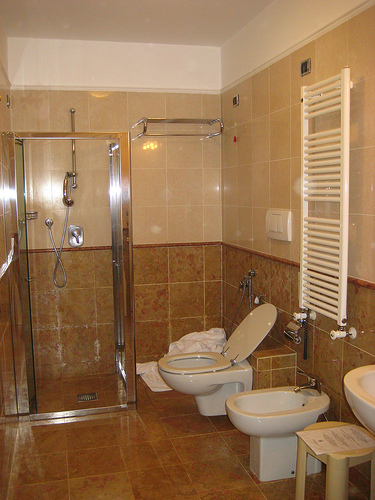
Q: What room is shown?
A: It is a bathroom.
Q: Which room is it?
A: It is a bathroom.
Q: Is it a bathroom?
A: Yes, it is a bathroom.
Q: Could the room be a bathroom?
A: Yes, it is a bathroom.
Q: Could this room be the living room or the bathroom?
A: It is the bathroom.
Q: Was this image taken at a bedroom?
A: No, the picture was taken in a bathroom.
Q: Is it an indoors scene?
A: Yes, it is indoors.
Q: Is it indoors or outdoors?
A: It is indoors.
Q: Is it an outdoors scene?
A: No, it is indoors.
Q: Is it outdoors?
A: No, it is indoors.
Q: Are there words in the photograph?
A: Yes, there are words.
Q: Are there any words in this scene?
A: Yes, there are words.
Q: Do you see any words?
A: Yes, there are words.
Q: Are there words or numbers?
A: Yes, there are words.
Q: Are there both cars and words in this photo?
A: No, there are words but no cars.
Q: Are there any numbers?
A: No, there are no numbers.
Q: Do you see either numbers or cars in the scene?
A: No, there are no numbers or cars.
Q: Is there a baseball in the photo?
A: No, there are no baseballs.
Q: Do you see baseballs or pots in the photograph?
A: No, there are no baseballs or pots.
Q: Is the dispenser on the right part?
A: Yes, the dispenser is on the right of the image.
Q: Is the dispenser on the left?
A: No, the dispenser is on the right of the image.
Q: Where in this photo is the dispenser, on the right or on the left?
A: The dispenser is on the right of the image.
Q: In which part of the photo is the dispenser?
A: The dispenser is on the right of the image.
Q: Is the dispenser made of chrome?
A: Yes, the dispenser is made of chrome.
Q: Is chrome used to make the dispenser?
A: Yes, the dispenser is made of chrome.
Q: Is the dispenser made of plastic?
A: No, the dispenser is made of chrome.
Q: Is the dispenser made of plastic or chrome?
A: The dispenser is made of chrome.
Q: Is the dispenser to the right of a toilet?
A: Yes, the dispenser is to the right of a toilet.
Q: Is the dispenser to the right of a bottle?
A: No, the dispenser is to the right of a toilet.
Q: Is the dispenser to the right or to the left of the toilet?
A: The dispenser is to the right of the toilet.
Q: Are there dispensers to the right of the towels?
A: Yes, there is a dispenser to the right of the towels.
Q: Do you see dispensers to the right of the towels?
A: Yes, there is a dispenser to the right of the towels.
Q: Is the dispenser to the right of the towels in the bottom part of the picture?
A: Yes, the dispenser is to the right of the towels.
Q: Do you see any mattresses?
A: No, there are no mattresses.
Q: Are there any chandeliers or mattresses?
A: No, there are no mattresses or chandeliers.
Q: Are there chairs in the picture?
A: No, there are no chairs.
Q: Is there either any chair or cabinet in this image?
A: No, there are no chairs or cabinets.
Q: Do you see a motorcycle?
A: No, there are no motorcycles.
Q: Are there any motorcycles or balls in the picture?
A: No, there are no motorcycles or balls.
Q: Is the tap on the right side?
A: Yes, the tap is on the right of the image.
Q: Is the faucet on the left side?
A: No, the faucet is on the right of the image.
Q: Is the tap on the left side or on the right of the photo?
A: The tap is on the right of the image.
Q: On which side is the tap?
A: The tap is on the right of the image.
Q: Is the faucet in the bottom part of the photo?
A: Yes, the faucet is in the bottom of the image.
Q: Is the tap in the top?
A: No, the tap is in the bottom of the image.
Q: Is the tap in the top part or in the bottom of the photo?
A: The tap is in the bottom of the image.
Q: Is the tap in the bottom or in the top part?
A: The tap is in the bottom of the image.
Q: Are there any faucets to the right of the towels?
A: Yes, there is a faucet to the right of the towels.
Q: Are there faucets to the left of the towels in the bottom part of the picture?
A: No, the faucet is to the right of the towels.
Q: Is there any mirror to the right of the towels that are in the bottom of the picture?
A: No, there is a faucet to the right of the towels.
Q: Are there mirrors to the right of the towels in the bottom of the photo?
A: No, there is a faucet to the right of the towels.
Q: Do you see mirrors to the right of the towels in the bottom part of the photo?
A: No, there is a faucet to the right of the towels.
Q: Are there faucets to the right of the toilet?
A: Yes, there is a faucet to the right of the toilet.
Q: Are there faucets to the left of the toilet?
A: No, the faucet is to the right of the toilet.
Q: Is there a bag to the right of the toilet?
A: No, there is a faucet to the right of the toilet.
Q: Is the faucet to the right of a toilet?
A: Yes, the faucet is to the right of a toilet.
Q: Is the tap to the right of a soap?
A: No, the tap is to the right of a toilet.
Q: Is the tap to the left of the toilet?
A: No, the tap is to the right of the toilet.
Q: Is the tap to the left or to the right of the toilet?
A: The tap is to the right of the toilet.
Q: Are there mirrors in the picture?
A: No, there are no mirrors.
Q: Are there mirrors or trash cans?
A: No, there are no mirrors or trash cans.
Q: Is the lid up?
A: Yes, the lid is up.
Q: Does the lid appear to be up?
A: Yes, the lid is up.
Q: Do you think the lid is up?
A: Yes, the lid is up.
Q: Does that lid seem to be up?
A: Yes, the lid is up.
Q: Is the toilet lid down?
A: No, the lid is up.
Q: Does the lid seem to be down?
A: No, the lid is up.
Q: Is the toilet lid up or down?
A: The lid is up.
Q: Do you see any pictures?
A: No, there are no pictures.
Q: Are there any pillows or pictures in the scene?
A: No, there are no pictures or pillows.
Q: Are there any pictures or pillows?
A: No, there are no pictures or pillows.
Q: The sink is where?
A: The sink is on the floor.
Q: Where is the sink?
A: The sink is on the floor.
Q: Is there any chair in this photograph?
A: No, there are no chairs.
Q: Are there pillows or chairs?
A: No, there are no chairs or pillows.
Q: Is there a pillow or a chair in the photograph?
A: No, there are no chairs or pillows.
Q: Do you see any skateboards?
A: No, there are no skateboards.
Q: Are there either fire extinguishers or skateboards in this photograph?
A: No, there are no skateboards or fire extinguishers.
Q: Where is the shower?
A: The shower is in the bathroom.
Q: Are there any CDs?
A: No, there are no cds.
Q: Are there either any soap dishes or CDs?
A: No, there are no CDs or soap dishes.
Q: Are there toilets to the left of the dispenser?
A: Yes, there is a toilet to the left of the dispenser.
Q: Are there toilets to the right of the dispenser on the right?
A: No, the toilet is to the left of the dispenser.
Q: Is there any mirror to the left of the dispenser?
A: No, there is a toilet to the left of the dispenser.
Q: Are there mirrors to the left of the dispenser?
A: No, there is a toilet to the left of the dispenser.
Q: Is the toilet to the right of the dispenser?
A: No, the toilet is to the left of the dispenser.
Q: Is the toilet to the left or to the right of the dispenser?
A: The toilet is to the left of the dispenser.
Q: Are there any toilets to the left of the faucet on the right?
A: Yes, there is a toilet to the left of the tap.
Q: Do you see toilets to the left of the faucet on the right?
A: Yes, there is a toilet to the left of the tap.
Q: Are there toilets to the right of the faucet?
A: No, the toilet is to the left of the faucet.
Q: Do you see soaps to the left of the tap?
A: No, there is a toilet to the left of the tap.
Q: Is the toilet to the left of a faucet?
A: Yes, the toilet is to the left of a faucet.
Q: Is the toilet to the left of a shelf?
A: No, the toilet is to the left of a faucet.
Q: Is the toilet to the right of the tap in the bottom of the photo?
A: No, the toilet is to the left of the faucet.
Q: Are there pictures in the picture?
A: No, there are no pictures.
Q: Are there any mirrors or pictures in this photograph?
A: No, there are no pictures or mirrors.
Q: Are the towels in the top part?
A: No, the towels are in the bottom of the image.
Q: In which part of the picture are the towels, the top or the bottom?
A: The towels are in the bottom of the image.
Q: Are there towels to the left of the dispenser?
A: Yes, there are towels to the left of the dispenser.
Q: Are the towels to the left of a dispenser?
A: Yes, the towels are to the left of a dispenser.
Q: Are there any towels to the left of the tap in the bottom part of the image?
A: Yes, there are towels to the left of the tap.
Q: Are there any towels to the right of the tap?
A: No, the towels are to the left of the tap.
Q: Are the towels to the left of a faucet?
A: Yes, the towels are to the left of a faucet.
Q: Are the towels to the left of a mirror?
A: No, the towels are to the left of a faucet.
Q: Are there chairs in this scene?
A: No, there are no chairs.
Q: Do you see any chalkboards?
A: No, there are no chalkboards.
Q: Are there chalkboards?
A: No, there are no chalkboards.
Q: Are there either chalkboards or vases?
A: No, there are no chalkboards or vases.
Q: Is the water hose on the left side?
A: Yes, the water hose is on the left of the image.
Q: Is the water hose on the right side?
A: No, the water hose is on the left of the image.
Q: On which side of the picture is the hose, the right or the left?
A: The hose is on the left of the image.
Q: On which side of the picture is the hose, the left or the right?
A: The hose is on the left of the image.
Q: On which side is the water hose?
A: The water hose is on the left of the image.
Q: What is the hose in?
A: The hose is in the shower.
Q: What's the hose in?
A: The hose is in the shower.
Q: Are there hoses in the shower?
A: Yes, there is a hose in the shower.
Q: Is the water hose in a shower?
A: Yes, the water hose is in a shower.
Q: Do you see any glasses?
A: No, there are no glasses.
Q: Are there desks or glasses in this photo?
A: No, there are no glasses or desks.